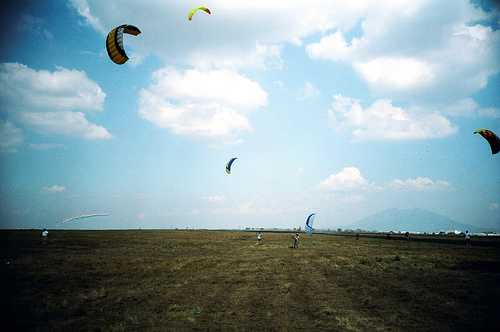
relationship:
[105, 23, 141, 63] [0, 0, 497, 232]
kite flying in sky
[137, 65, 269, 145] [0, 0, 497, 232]
cloud floating in sky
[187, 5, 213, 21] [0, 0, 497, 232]
kite flying in sky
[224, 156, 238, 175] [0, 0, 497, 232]
kite flying in sky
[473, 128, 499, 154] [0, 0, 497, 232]
kite flying in sky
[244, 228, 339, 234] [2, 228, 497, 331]
trees behind field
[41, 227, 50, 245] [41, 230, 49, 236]
man wearing shirt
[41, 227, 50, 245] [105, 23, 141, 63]
man flying kite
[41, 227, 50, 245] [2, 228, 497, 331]
man walking in field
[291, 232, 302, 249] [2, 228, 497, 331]
man walking in field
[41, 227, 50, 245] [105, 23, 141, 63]
man testing kite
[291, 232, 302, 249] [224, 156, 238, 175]
man testing kite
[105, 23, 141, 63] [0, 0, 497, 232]
kite flying in air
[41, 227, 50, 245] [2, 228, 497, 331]
man standing in field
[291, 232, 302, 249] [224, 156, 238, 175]
man flying kite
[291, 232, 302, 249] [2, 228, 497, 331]
man standing in field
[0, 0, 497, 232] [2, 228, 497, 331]
sky over field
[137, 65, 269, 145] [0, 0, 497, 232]
cloud in sky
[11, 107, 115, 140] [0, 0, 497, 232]
cloud in sky